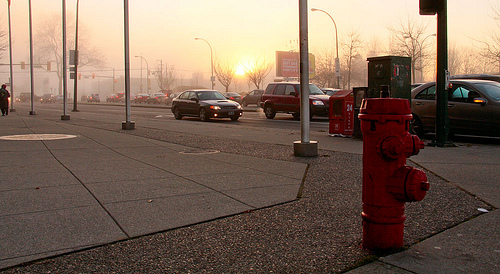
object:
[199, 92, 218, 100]
people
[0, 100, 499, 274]
road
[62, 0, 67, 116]
pole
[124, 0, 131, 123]
pole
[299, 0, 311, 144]
pole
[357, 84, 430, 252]
hydrant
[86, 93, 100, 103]
cars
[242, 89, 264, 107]
car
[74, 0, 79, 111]
pole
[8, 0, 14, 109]
pole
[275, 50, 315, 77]
advertisement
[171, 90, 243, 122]
bus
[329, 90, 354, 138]
newspaper stand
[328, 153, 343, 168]
ground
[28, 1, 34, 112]
pole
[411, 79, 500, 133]
car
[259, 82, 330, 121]
car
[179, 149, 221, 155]
cover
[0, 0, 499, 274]
city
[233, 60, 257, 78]
sundown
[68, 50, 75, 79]
laws